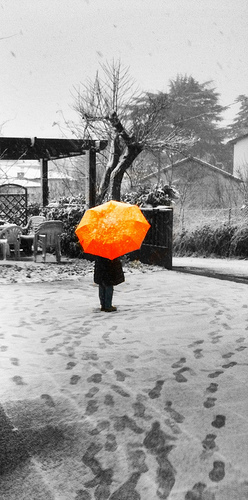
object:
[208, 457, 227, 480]
footprint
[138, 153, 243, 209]
building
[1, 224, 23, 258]
chairs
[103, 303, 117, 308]
boots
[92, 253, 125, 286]
coat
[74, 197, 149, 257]
umbrella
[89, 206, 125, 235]
snow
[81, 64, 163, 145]
branches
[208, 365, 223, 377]
prints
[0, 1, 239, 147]
sky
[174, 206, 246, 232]
fence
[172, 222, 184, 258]
bushes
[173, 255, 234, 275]
snow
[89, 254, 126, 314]
person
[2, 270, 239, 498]
snow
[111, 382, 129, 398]
footprints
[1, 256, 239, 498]
ground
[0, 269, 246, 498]
pavement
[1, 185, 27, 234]
trellis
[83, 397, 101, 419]
footprints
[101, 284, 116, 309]
legs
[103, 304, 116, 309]
feet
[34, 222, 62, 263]
chair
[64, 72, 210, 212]
tree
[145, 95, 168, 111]
leaves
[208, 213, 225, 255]
bush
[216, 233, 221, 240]
leaves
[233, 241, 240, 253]
leaves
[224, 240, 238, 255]
leaves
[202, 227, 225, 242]
leaves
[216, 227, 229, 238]
leaves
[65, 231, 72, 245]
leaves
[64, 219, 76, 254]
bush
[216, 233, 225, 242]
leaves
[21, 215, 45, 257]
chair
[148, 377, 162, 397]
footprint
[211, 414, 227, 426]
footprint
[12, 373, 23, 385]
footprint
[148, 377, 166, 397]
footprint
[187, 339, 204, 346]
footprint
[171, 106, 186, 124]
leaves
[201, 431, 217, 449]
footprint